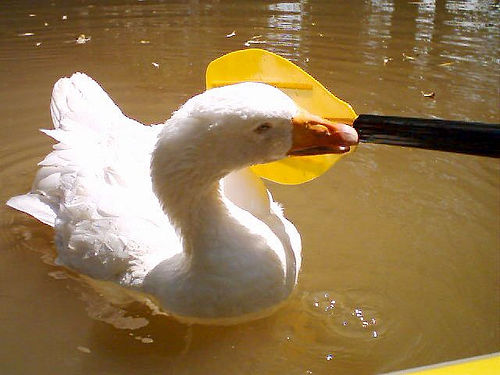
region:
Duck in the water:
[26, 53, 405, 348]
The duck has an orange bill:
[282, 105, 377, 159]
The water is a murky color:
[357, 209, 493, 328]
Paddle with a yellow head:
[196, 19, 406, 222]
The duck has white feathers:
[82, 125, 205, 249]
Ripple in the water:
[304, 268, 429, 352]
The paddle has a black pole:
[375, 103, 492, 148]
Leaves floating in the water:
[51, 15, 178, 59]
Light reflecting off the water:
[305, 2, 495, 74]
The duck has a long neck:
[127, 153, 274, 259]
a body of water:
[332, 175, 487, 371]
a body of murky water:
[357, 171, 496, 359]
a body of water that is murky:
[297, 194, 499, 344]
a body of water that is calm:
[324, 176, 468, 361]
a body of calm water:
[317, 163, 484, 363]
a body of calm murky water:
[327, 219, 457, 356]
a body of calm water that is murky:
[314, 188, 464, 370]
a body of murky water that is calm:
[311, 196, 480, 373]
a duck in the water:
[73, 36, 444, 365]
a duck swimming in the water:
[87, 28, 459, 372]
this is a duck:
[5, 5, 370, 367]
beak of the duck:
[280, 95, 362, 172]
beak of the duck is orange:
[275, 92, 374, 184]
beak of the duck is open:
[277, 97, 371, 179]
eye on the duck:
[237, 94, 277, 142]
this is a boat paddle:
[197, 16, 497, 268]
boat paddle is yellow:
[186, 28, 367, 199]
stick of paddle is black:
[340, 97, 494, 198]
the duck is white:
[29, 47, 376, 339]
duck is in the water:
[19, 10, 457, 371]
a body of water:
[126, 9, 300, 79]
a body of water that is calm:
[365, 214, 497, 331]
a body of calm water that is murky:
[414, 169, 493, 320]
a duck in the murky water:
[26, 56, 408, 368]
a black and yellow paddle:
[184, 6, 468, 249]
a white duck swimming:
[22, 16, 433, 371]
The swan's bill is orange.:
[292, 97, 360, 168]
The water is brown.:
[374, 227, 482, 337]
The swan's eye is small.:
[257, 119, 273, 136]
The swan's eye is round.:
[252, 117, 273, 133]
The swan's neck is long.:
[146, 105, 244, 245]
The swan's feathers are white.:
[8, 68, 356, 332]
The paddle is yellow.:
[204, 40, 356, 189]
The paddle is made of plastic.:
[197, 45, 362, 190]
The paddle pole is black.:
[354, 111, 499, 163]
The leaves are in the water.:
[52, 12, 130, 47]